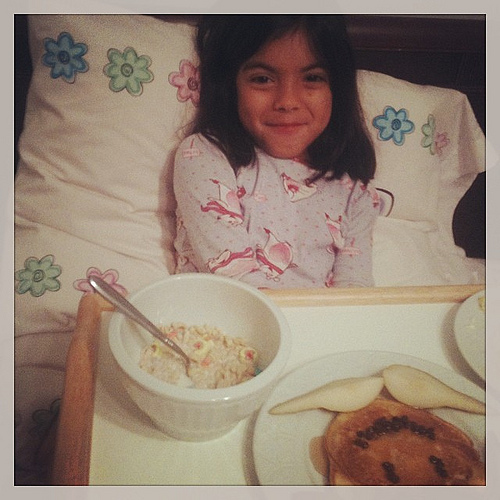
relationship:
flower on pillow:
[369, 102, 418, 146] [17, 4, 489, 367]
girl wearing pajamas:
[170, 14, 381, 293] [175, 152, 365, 267]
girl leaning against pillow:
[170, 14, 381, 293] [18, 17, 460, 274]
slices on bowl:
[283, 350, 457, 460] [106, 271, 292, 444]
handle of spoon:
[88, 273, 191, 363] [85, 275, 221, 391]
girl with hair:
[140, 36, 435, 363] [207, 25, 380, 182]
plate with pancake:
[247, 344, 487, 486] [318, 397, 485, 481]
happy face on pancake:
[348, 411, 460, 492] [304, 401, 499, 498]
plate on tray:
[453, 290, 485, 382] [51, 283, 486, 485]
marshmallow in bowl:
[242, 343, 257, 363] [103, 269, 295, 446]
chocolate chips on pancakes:
[352, 413, 435, 448] [320, 401, 494, 486]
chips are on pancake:
[349, 416, 435, 443] [331, 397, 474, 488]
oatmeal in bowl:
[138, 319, 260, 389] [103, 269, 295, 446]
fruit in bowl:
[197, 335, 217, 364] [141, 390, 230, 435]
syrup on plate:
[308, 432, 329, 476] [304, 365, 368, 372]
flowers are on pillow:
[17, 39, 449, 309] [15, 14, 485, 336]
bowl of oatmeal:
[103, 269, 295, 446] [189, 324, 235, 371]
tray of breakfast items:
[81, 257, 469, 489] [80, 285, 475, 459]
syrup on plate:
[309, 432, 329, 476] [247, 344, 487, 486]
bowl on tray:
[103, 269, 295, 446] [51, 283, 486, 485]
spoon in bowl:
[87, 277, 209, 384] [103, 269, 295, 446]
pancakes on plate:
[327, 400, 469, 482] [252, 396, 295, 481]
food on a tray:
[107, 270, 488, 484] [70, 302, 487, 482]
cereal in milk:
[134, 320, 266, 392] [136, 319, 263, 393]